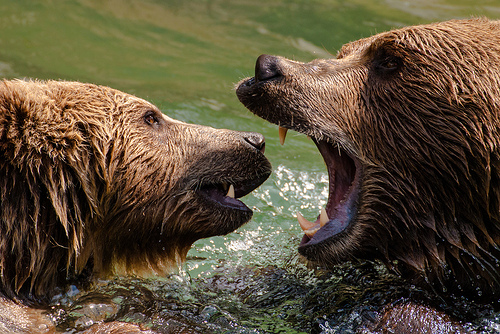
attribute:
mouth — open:
[206, 150, 257, 219]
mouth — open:
[219, 69, 388, 241]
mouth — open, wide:
[231, 70, 353, 253]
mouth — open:
[209, 140, 272, 232]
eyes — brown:
[120, 104, 186, 154]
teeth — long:
[286, 203, 352, 236]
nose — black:
[240, 43, 286, 89]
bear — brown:
[45, 68, 263, 237]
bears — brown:
[41, 56, 437, 257]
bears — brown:
[81, 64, 444, 272]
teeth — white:
[274, 119, 289, 148]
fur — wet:
[406, 112, 447, 191]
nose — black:
[240, 60, 301, 97]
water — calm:
[76, 22, 248, 108]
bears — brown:
[54, 49, 482, 295]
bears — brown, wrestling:
[21, 47, 437, 316]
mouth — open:
[225, 57, 403, 278]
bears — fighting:
[43, 25, 440, 296]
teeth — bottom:
[272, 202, 340, 258]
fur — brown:
[16, 87, 76, 187]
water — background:
[60, 28, 254, 111]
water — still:
[106, 6, 247, 133]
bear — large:
[204, 43, 462, 285]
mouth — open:
[255, 120, 380, 300]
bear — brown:
[33, 80, 250, 270]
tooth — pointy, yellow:
[274, 190, 343, 259]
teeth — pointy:
[272, 210, 364, 277]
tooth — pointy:
[214, 150, 253, 185]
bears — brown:
[49, 33, 416, 196]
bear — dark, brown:
[234, 20, 463, 267]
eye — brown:
[128, 110, 178, 142]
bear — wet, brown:
[32, 60, 314, 291]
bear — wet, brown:
[222, 36, 427, 254]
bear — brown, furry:
[208, 47, 448, 234]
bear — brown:
[228, 13, 498, 333]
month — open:
[222, 80, 376, 272]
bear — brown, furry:
[1, 65, 278, 326]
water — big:
[1, 1, 498, 332]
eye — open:
[139, 99, 163, 129]